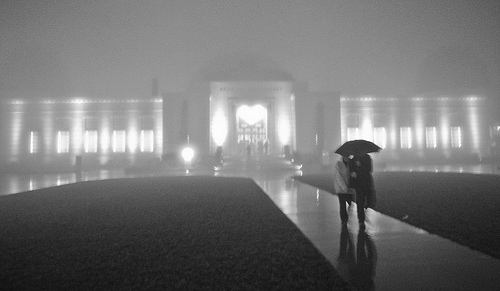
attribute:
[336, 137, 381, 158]
umbrella — black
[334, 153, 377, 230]
people — standing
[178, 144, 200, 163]
light — bright, white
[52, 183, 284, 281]
grass — cut, neat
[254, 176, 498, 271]
sidewalk — wet, gray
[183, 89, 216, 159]
pillars — white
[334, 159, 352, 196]
coat — white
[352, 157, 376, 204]
clothes — dark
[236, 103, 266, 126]
lights — bright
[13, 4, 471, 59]
sky — black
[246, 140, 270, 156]
people — standing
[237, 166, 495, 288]
pavement — wet, glistening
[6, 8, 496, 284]
picture — black, white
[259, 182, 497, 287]
road — wet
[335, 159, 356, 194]
coat — white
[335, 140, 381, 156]
umbrella — dark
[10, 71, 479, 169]
building — wide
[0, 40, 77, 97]
dome — barely visible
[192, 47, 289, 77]
dome — barely visible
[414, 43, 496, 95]
dome — barely visible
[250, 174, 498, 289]
sidewalk — wet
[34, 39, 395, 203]
scene — gloomy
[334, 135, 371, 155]
umbrella — single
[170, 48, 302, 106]
words — blurred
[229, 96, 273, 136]
window — heart shaped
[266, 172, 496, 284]
sidewalk — wet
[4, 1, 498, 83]
sky — dark, grey, gloomy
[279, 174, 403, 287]
walkway — Rain-covered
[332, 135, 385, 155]
umbrella — black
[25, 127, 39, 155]
window — tall, rectangular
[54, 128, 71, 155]
window — tall, rectangular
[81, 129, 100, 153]
window — tall, rectangular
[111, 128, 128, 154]
window — tall, rectangular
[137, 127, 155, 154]
window — tall, rectangular